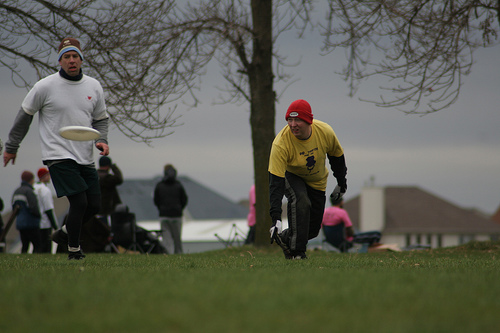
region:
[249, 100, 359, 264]
man wearing yellow shirt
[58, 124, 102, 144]
white frisbee moving through the air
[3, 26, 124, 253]
man wearing white tshirt and gray long sleeve shirt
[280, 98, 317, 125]
red knit cap man is wearing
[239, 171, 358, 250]
two people wearing pink shirts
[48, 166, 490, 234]
mountains in the distance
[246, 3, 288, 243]
tree trunk behind man in yellow shirt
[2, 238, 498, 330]
grass field men are running on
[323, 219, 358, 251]
black chair man is sitting in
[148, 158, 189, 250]
person wearing black hooded jacket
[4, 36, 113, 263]
this is a person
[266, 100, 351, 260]
this is a person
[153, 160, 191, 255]
this is a person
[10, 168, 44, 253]
this is a person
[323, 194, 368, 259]
this is a person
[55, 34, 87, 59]
this is a hat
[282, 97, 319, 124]
this is a hat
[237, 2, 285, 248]
this is a stem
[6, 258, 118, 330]
this is green vegetation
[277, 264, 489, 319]
this is green vegetation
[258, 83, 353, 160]
a man wearing a red hat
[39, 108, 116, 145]
a white frisbee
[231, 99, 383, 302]
a man standing on the grass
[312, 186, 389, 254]
a person sitting in a chair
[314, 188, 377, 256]
a person wearing a pink shirt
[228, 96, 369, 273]
a man wearing black pants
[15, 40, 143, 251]
a man playing frisbee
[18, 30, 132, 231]
a man wearing a white shirt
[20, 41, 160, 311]
a man wearing shorts over pants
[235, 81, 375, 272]
a man wearing a yellow shirt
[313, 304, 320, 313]
part of a field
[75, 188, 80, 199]
part of a short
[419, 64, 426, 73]
part of a branch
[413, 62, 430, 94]
part of a twig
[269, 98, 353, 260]
players watches the frisbee he just threw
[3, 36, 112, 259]
player watches frisbee fly through the air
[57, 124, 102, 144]
frisbee flies through the air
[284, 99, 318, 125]
hat is worn by player for warmth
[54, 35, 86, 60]
hat is worn by player for warmth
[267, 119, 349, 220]
two shirts are worn by player for warmth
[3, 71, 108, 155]
two shirts are worn by player for warmth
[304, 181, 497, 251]
building is in background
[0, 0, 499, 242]
tree is in background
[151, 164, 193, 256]
human walks in the distance